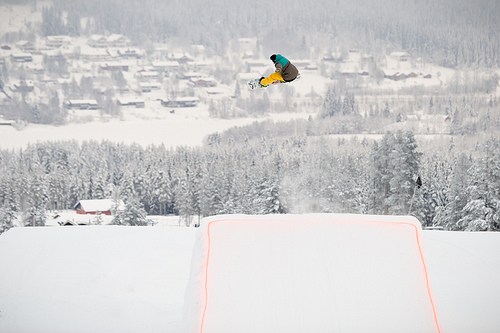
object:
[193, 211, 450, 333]
jump ramp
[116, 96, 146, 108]
houses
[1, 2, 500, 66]
trees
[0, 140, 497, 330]
mountain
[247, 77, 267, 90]
snowboard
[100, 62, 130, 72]
houses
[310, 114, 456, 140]
ground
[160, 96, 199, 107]
buildings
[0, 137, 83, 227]
trees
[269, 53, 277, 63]
hat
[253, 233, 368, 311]
snow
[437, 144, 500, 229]
trees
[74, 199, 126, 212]
roof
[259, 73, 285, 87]
pants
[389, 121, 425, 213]
pine tree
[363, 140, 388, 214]
pine tree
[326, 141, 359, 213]
pine tree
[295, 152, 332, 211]
pine tree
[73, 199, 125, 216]
building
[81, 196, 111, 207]
snow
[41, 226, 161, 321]
snow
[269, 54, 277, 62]
head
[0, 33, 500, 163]
village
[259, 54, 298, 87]
coat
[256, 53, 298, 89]
he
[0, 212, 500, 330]
ground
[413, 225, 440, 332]
line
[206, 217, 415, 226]
line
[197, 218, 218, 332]
line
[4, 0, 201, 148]
snow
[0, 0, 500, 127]
hill